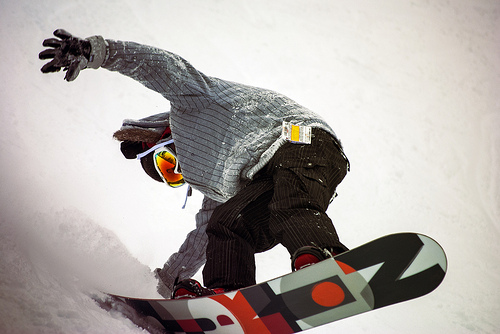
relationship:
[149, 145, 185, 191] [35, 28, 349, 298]
reflective goggles on man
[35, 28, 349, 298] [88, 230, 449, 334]
man on board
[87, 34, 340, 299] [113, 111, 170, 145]
jacket has hood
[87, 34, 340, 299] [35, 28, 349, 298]
jacket on man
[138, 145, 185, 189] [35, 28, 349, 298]
helmet on man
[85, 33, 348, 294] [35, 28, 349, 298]
outfit on man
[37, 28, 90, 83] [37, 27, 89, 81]
glove on hand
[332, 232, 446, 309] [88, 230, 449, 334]
letter n on board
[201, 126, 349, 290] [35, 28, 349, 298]
pants on man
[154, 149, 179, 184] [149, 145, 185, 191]
color orange on reflective goggles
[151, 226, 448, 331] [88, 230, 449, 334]
decorations on board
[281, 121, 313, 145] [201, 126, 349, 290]
tag on pants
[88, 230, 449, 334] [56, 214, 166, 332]
board in snow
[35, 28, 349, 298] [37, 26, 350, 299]
man wearing snow gear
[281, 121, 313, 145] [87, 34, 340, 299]
tag on jacket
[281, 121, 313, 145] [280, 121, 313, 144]
tag has snow time allowance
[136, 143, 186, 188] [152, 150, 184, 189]
snowboarders face has mirror lens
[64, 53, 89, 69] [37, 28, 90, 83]
snow on glove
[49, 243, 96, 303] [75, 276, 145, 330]
snow on snow board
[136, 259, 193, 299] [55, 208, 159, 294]
arm in snow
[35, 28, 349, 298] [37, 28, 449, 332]
man doing a trick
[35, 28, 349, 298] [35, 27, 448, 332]
man doing tricks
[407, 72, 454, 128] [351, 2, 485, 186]
white clouds in sky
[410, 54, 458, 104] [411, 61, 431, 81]
sky has white clouds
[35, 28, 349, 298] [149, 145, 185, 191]
man wearing reflective goggles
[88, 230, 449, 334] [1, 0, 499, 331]
board in snow